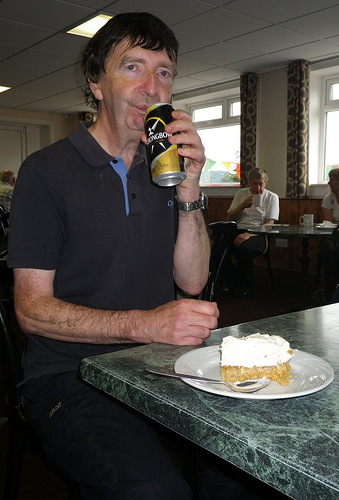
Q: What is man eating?
A: Cake.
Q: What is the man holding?
A: A beer.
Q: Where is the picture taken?
A: A diner.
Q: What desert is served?
A: Pie.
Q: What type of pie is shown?
A: Coconut.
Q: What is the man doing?
A: Drinking.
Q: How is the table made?
A: Of marble.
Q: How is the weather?
A: Sunny.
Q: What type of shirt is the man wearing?
A: Short sleeved.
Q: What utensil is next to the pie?
A: Spoon.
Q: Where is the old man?
A: At a restaurant.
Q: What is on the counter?
A: A plate.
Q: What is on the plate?
A: A slice of cake.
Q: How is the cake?
A: Topped with white cream.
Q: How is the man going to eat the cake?
A: With the spoon.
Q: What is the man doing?
A: Drinking.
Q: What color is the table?
A: Green.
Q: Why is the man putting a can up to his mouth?
A: He is drinking a beverage.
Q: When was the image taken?
A: During the day.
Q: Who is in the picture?
A: People eating.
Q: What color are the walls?
A: White.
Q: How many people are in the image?
A: Four.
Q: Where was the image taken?
A: In a restaurant.